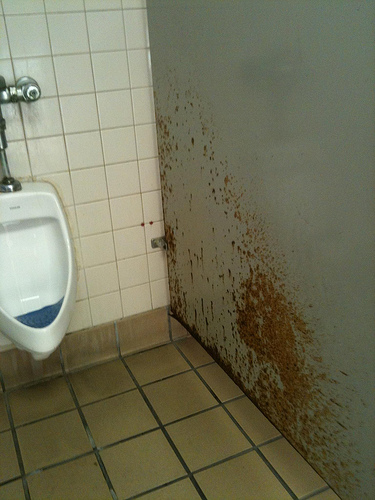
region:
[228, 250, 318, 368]
rust on stall wall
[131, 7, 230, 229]
stall wall in bathroom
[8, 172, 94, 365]
white urinal on wall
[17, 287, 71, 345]
blue in base of urinal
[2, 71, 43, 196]
silver hardware on wall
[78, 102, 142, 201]
square white tiles on wall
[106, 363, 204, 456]
tiles on bathroom floor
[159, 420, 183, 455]
grout in between tiles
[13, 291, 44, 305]
light reflection on urinal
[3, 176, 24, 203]
light reflection on metal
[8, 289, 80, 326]
the water is blue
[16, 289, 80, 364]
the water is blue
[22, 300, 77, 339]
the water is blue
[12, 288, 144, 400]
the water is blue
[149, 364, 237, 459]
the tile is fading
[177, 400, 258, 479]
the tile is fading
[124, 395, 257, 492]
the tile is fading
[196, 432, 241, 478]
the tile is fading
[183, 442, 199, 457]
the tile is fading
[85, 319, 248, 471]
the tile is fading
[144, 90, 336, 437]
Rust on the divider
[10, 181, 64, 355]
A urinal in the bathroom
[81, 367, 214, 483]
Brown bathroom floor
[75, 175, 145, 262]
Tile on the wall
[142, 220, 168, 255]
Bolt connecting the divider to the wall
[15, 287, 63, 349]
Blue mat in the urinal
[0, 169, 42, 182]
Plumbing for the urinal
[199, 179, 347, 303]
Gray divider in the bathroom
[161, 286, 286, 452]
Very rusty bottom of the divider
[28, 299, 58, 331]
Bue drain catcher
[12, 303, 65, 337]
Blue drain mat in the urinal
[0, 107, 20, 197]
Plumbing for the urinal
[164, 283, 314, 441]
Heavy rust on the divider bottom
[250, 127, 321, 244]
Grey rusty divder wall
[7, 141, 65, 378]
Commercial bathroom urinal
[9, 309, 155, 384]
Water stains on the wall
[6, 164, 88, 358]
White urinal on the wall